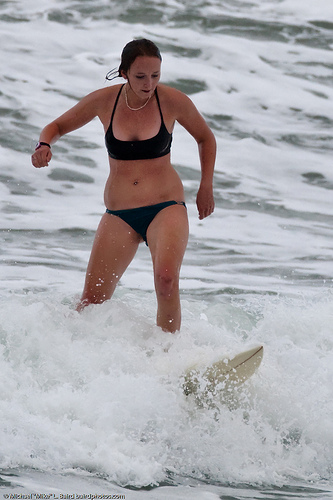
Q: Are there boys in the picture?
A: No, there are no boys.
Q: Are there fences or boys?
A: No, there are no boys or fences.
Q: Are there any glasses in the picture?
A: No, there are no glasses.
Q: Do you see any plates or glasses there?
A: No, there are no glasses or plates.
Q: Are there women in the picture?
A: Yes, there is a woman.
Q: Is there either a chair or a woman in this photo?
A: Yes, there is a woman.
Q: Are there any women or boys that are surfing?
A: Yes, the woman is surfing.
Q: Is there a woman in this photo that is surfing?
A: Yes, there is a woman that is surfing.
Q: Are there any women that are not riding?
A: Yes, there is a woman that is surfing.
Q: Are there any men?
A: No, there are no men.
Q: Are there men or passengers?
A: No, there are no men or passengers.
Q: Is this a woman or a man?
A: This is a woman.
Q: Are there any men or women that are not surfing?
A: No, there is a woman but she is surfing.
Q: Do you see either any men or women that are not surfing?
A: No, there is a woman but she is surfing.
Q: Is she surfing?
A: Yes, the woman is surfing.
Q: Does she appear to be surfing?
A: Yes, the woman is surfing.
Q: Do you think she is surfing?
A: Yes, the woman is surfing.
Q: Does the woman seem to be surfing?
A: Yes, the woman is surfing.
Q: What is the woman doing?
A: The woman is surfing.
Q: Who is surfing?
A: The woman is surfing.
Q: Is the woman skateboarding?
A: No, the woman is surfing.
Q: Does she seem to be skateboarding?
A: No, the woman is surfing.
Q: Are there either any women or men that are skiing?
A: No, there is a woman but she is surfing.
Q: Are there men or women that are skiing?
A: No, there is a woman but she is surfing.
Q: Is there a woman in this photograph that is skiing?
A: No, there is a woman but she is surfing.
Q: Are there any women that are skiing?
A: No, there is a woman but she is surfing.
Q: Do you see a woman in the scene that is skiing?
A: No, there is a woman but she is surfing.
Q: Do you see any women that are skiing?
A: No, there is a woman but she is surfing.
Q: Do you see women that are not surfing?
A: No, there is a woman but she is surfing.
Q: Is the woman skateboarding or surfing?
A: The woman is surfing.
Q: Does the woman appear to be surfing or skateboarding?
A: The woman is surfing.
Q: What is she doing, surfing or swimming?
A: The woman is surfing.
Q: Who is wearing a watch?
A: The woman is wearing a watch.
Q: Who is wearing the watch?
A: The woman is wearing a watch.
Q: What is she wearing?
A: The woman is wearing a watch.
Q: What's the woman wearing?
A: The woman is wearing a watch.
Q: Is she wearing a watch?
A: Yes, the woman is wearing a watch.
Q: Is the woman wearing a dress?
A: No, the woman is wearing a watch.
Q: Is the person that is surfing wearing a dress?
A: No, the woman is wearing a watch.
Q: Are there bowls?
A: No, there are no bowls.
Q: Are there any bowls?
A: No, there are no bowls.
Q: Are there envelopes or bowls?
A: No, there are no bowls or envelopes.